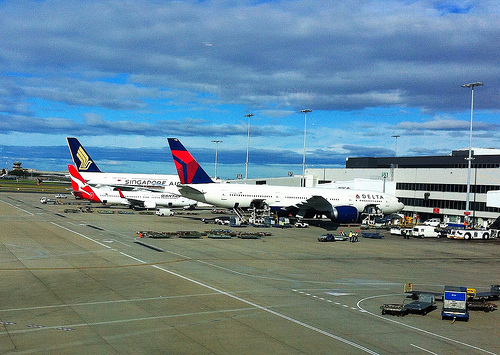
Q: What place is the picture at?
A: It is at the airport.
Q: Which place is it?
A: It is an airport.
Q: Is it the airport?
A: Yes, it is the airport.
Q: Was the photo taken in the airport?
A: Yes, it was taken in the airport.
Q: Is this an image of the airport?
A: Yes, it is showing the airport.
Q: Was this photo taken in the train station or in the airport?
A: It was taken at the airport.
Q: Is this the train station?
A: No, it is the airport.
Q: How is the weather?
A: It is cloudy.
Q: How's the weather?
A: It is cloudy.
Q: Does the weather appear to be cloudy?
A: Yes, it is cloudy.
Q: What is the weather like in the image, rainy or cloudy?
A: It is cloudy.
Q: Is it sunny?
A: No, it is cloudy.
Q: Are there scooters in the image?
A: No, there are no scooters.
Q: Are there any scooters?
A: No, there are no scooters.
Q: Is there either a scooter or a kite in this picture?
A: No, there are no scooters or kites.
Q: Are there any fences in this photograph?
A: No, there are no fences.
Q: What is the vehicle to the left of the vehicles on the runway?
A: The vehicle is a van.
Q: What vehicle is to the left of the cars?
A: The vehicle is a van.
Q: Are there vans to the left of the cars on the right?
A: Yes, there is a van to the left of the cars.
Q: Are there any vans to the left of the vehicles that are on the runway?
A: Yes, there is a van to the left of the cars.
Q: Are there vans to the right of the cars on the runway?
A: No, the van is to the left of the cars.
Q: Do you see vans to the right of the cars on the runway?
A: No, the van is to the left of the cars.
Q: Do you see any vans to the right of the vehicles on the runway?
A: No, the van is to the left of the cars.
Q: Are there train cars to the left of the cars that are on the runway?
A: No, there is a van to the left of the cars.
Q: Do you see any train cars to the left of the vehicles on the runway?
A: No, there is a van to the left of the cars.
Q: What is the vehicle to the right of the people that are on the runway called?
A: The vehicle is a van.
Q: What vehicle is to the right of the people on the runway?
A: The vehicle is a van.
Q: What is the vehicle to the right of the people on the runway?
A: The vehicle is a van.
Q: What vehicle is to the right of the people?
A: The vehicle is a van.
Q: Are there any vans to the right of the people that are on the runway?
A: Yes, there is a van to the right of the people.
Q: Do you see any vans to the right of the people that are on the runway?
A: Yes, there is a van to the right of the people.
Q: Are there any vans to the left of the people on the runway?
A: No, the van is to the right of the people.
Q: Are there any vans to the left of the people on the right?
A: No, the van is to the right of the people.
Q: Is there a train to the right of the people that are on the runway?
A: No, there is a van to the right of the people.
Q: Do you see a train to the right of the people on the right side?
A: No, there is a van to the right of the people.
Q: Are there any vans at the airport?
A: Yes, there is a van at the airport.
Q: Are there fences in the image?
A: No, there are no fences.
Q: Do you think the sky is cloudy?
A: Yes, the sky is cloudy.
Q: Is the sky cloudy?
A: Yes, the sky is cloudy.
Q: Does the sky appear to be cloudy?
A: Yes, the sky is cloudy.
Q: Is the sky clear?
A: No, the sky is cloudy.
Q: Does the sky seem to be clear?
A: No, the sky is cloudy.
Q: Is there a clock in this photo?
A: No, there are no clocks.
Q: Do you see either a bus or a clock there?
A: No, there are no clocks or buses.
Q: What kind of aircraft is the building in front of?
A: The building is in front of the airplane.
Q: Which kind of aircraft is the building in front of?
A: The building is in front of the airplane.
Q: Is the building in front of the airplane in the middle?
A: Yes, the building is in front of the airplane.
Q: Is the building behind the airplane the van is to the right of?
A: No, the building is in front of the plane.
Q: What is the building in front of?
A: The building is in front of the plane.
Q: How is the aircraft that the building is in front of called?
A: The aircraft is an airplane.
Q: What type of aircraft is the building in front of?
A: The building is in front of the airplane.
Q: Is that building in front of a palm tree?
A: No, the building is in front of an airplane.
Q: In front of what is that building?
A: The building is in front of the airplane.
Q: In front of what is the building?
A: The building is in front of the airplane.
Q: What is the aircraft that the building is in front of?
A: The aircraft is an airplane.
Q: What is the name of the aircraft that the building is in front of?
A: The aircraft is an airplane.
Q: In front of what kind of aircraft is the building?
A: The building is in front of the airplane.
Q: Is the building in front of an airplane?
A: Yes, the building is in front of an airplane.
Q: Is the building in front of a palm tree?
A: No, the building is in front of an airplane.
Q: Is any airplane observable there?
A: Yes, there is an airplane.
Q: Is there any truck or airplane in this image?
A: Yes, there is an airplane.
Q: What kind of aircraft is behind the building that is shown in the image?
A: The aircraft is an airplane.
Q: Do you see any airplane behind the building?
A: Yes, there is an airplane behind the building.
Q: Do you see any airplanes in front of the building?
A: No, the airplane is behind the building.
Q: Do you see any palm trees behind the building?
A: No, there is an airplane behind the building.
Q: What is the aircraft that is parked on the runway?
A: The aircraft is an airplane.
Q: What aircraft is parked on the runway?
A: The aircraft is an airplane.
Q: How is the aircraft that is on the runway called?
A: The aircraft is an airplane.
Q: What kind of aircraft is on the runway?
A: The aircraft is an airplane.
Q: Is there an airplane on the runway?
A: Yes, there is an airplane on the runway.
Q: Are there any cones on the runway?
A: No, there is an airplane on the runway.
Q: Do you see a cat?
A: No, there are no cats.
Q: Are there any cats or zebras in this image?
A: No, there are no cats or zebras.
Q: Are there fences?
A: No, there are no fences.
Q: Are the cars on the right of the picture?
A: Yes, the cars are on the right of the image.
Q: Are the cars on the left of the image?
A: No, the cars are on the right of the image.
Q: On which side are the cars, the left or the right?
A: The cars are on the right of the image.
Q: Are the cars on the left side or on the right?
A: The cars are on the right of the image.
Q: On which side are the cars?
A: The cars are on the right of the image.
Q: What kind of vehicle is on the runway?
A: The vehicles are cars.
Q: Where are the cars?
A: The cars are on the runway.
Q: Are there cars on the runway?
A: Yes, there are cars on the runway.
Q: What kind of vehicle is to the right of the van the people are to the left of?
A: The vehicles are cars.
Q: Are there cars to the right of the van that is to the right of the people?
A: Yes, there are cars to the right of the van.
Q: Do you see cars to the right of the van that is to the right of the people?
A: Yes, there are cars to the right of the van.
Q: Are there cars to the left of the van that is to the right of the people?
A: No, the cars are to the right of the van.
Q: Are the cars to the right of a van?
A: Yes, the cars are to the right of a van.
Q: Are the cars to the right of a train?
A: No, the cars are to the right of a van.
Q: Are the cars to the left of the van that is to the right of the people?
A: No, the cars are to the right of the van.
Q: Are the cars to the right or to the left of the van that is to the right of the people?
A: The cars are to the right of the van.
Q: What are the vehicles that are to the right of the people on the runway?
A: The vehicles are cars.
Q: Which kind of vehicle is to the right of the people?
A: The vehicles are cars.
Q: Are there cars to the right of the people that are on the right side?
A: Yes, there are cars to the right of the people.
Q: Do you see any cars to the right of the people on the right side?
A: Yes, there are cars to the right of the people.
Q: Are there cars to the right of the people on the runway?
A: Yes, there are cars to the right of the people.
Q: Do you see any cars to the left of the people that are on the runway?
A: No, the cars are to the right of the people.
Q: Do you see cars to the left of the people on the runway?
A: No, the cars are to the right of the people.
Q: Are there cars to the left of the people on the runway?
A: No, the cars are to the right of the people.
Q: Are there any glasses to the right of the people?
A: No, there are cars to the right of the people.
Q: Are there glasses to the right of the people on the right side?
A: No, there are cars to the right of the people.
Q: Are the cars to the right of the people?
A: Yes, the cars are to the right of the people.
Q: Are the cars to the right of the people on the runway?
A: Yes, the cars are to the right of the people.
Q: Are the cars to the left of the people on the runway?
A: No, the cars are to the right of the people.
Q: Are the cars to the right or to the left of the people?
A: The cars are to the right of the people.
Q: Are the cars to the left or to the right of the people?
A: The cars are to the right of the people.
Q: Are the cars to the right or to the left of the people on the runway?
A: The cars are to the right of the people.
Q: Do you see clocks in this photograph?
A: No, there are no clocks.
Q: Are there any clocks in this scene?
A: No, there are no clocks.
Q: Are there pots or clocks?
A: No, there are no clocks or pots.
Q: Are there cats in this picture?
A: No, there are no cats.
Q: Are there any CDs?
A: No, there are no cds.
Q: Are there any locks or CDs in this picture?
A: No, there are no CDs or locks.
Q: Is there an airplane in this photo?
A: Yes, there is an airplane.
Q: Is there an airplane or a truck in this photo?
A: Yes, there is an airplane.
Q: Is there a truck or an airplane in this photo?
A: Yes, there is an airplane.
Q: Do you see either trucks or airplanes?
A: Yes, there is an airplane.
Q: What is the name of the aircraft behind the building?
A: The aircraft is an airplane.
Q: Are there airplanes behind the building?
A: Yes, there is an airplane behind the building.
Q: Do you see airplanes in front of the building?
A: No, the airplane is behind the building.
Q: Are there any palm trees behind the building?
A: No, there is an airplane behind the building.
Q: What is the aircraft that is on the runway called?
A: The aircraft is an airplane.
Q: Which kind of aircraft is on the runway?
A: The aircraft is an airplane.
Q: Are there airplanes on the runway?
A: Yes, there is an airplane on the runway.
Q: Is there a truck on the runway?
A: No, there is an airplane on the runway.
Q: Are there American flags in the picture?
A: No, there are no American flags.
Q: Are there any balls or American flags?
A: No, there are no American flags or balls.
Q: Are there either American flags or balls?
A: No, there are no American flags or balls.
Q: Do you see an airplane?
A: Yes, there is an airplane.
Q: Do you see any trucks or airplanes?
A: Yes, there is an airplane.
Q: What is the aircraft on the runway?
A: The aircraft is an airplane.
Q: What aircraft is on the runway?
A: The aircraft is an airplane.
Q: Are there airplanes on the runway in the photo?
A: Yes, there is an airplane on the runway.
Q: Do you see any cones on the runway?
A: No, there is an airplane on the runway.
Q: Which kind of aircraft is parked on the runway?
A: The aircraft is an airplane.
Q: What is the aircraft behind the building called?
A: The aircraft is an airplane.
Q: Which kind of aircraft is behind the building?
A: The aircraft is an airplane.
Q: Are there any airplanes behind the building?
A: Yes, there is an airplane behind the building.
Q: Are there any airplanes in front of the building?
A: No, the airplane is behind the building.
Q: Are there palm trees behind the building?
A: No, there is an airplane behind the building.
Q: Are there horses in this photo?
A: No, there are no horses.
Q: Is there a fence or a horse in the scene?
A: No, there are no horses or fences.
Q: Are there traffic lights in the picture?
A: No, there are no traffic lights.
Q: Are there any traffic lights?
A: No, there are no traffic lights.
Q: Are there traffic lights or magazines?
A: No, there are no traffic lights or magazines.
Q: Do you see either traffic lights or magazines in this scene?
A: No, there are no traffic lights or magazines.